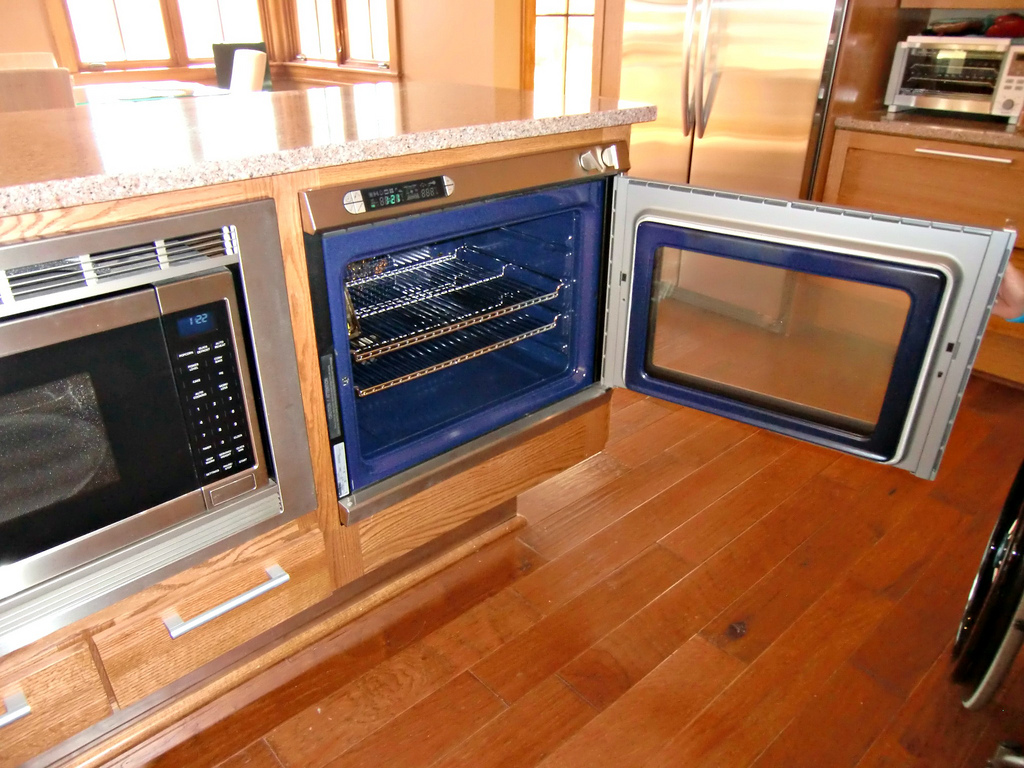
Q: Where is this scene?
A: In a kitchen.